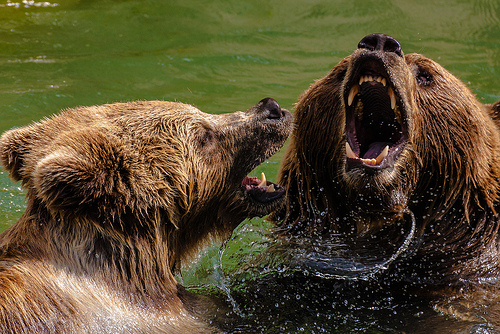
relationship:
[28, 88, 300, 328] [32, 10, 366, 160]
bear in water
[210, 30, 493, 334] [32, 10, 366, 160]
bear in water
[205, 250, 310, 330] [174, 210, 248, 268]
water dripping off bear's fur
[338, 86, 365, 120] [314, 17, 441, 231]
tooth in a mouth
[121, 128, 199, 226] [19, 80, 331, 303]
fur on a bear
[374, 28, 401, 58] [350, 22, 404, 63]
nostrils on a nose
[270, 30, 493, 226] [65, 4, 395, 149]
bear playing in water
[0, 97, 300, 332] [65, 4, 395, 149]
bear playing in water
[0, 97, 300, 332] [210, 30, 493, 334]
bear play fighting bear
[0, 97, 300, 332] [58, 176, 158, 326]
bear has fur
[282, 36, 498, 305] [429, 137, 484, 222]
bear has fur